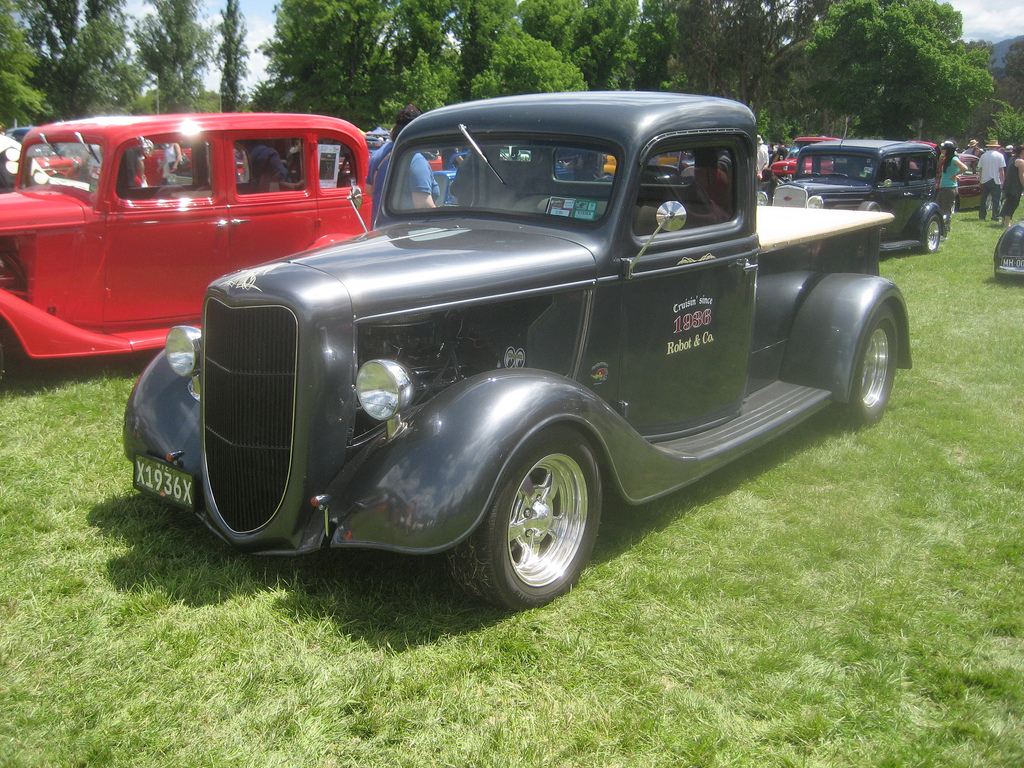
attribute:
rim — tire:
[502, 445, 585, 585]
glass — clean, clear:
[388, 133, 622, 219]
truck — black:
[117, 90, 928, 615]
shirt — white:
[964, 148, 991, 190]